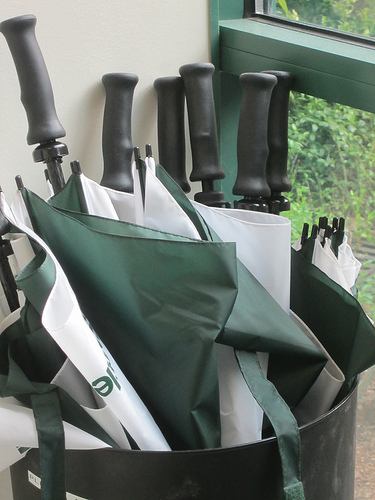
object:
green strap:
[29, 392, 70, 498]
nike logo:
[226, 31, 365, 67]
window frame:
[204, 0, 373, 223]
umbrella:
[0, 10, 374, 500]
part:
[277, 426, 298, 449]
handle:
[1, 13, 67, 139]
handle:
[178, 60, 226, 180]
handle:
[231, 68, 280, 200]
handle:
[151, 74, 189, 191]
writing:
[80, 310, 123, 397]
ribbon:
[235, 348, 307, 498]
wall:
[0, 0, 213, 206]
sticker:
[24, 464, 86, 498]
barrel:
[10, 376, 355, 498]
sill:
[220, 23, 372, 110]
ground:
[360, 432, 371, 456]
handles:
[265, 69, 294, 194]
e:
[89, 373, 115, 399]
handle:
[100, 67, 138, 195]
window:
[205, 4, 374, 306]